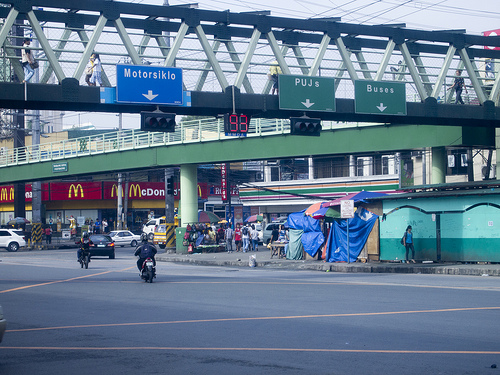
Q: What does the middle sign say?
A: PUJs.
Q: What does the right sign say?
A: Buses.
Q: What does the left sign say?
A: Motorsiklo.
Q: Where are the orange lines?
A: On road.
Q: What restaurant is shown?
A: McDonalds.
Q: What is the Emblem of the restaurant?
A: Golden M.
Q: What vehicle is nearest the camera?
A: Motorcycle.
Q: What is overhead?
A: A walkway.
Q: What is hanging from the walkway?
A: Signs.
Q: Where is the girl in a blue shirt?
A: On the sidewalk.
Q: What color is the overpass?
A: Green.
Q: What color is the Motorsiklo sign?
A: Blue.